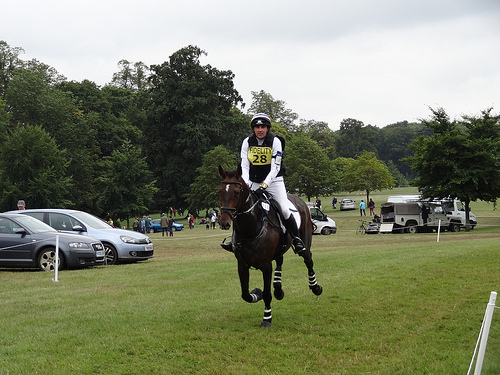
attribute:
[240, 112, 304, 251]
man — riding, looking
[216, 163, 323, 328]
horse — brown, totting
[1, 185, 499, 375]
field — trimmed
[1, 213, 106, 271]
car — parked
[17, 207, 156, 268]
car — parked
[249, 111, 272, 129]
helmet — gray, white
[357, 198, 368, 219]
person — standing, wandering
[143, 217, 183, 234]
car — blue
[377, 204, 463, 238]
truck — parked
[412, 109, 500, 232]
tree — distant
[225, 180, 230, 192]
spot — white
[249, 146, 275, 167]
sign — yellow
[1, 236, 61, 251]
fence — white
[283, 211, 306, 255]
boot — black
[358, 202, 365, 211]
shirt — green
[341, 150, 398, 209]
tree — distant, green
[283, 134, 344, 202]
tree — tall, distant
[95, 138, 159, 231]
tree — distant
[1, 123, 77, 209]
tree — distant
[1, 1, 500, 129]
sky — cloudy